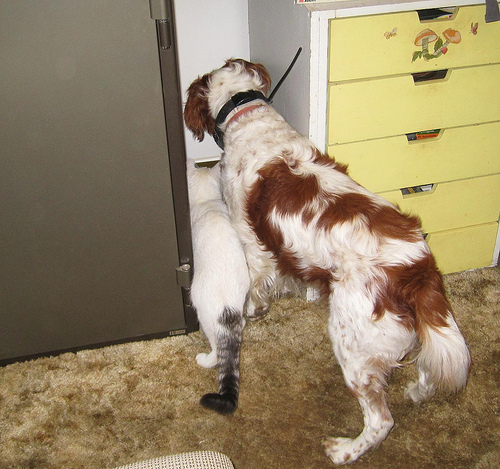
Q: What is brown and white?
A: Dog.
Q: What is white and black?
A: Cat.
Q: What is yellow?
A: Drawers.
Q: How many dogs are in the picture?
A: One.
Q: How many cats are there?
A: Only one.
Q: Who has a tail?
A: Dog and cat.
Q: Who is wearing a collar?
A: The dog.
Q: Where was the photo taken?
A: In a bedroom.